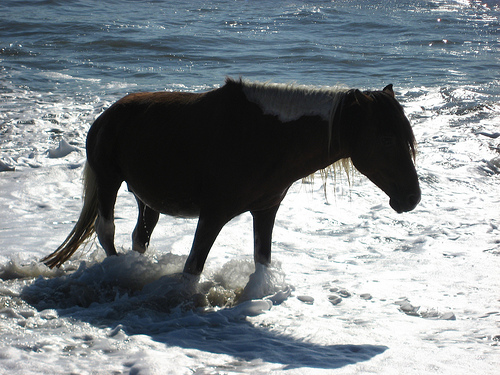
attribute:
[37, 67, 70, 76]
foam — white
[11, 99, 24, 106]
foam — white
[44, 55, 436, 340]
horse — brown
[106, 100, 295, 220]
horse — brown